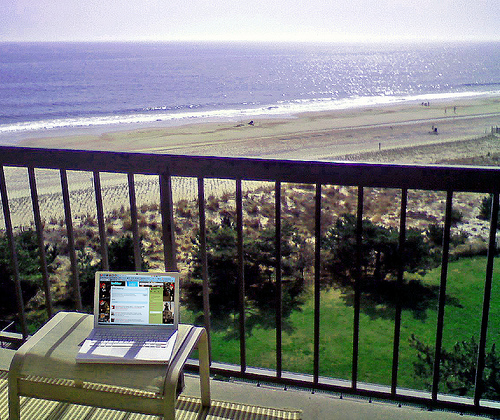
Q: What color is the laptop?
A: White.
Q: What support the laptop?
A: Foot rest.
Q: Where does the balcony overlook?
A: Yard and beach.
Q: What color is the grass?
A: Green.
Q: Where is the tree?
A: By the beach.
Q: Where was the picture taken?
A: On a balcony.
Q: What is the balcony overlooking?
A: The beach.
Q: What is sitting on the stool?
A: A computer.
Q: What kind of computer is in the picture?
A: A laptop.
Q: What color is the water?
A: Blue.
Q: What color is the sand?
A: Tan.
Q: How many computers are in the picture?
A: One.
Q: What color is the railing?
A: Black.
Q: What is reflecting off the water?
A: The sun.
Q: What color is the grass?
A: Green.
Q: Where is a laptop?
A: On a foot stool.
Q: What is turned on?
A: Laptop computer.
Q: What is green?
A: Grass.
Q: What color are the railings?
A: Black.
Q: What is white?
A: The laptop.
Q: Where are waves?
A: In the ocean.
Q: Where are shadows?
A: On the grass.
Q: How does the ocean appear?
A: Calm.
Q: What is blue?
A: The ocean water.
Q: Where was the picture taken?
A: On a balcony.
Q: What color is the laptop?
A: White.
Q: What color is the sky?
A: Blue and white.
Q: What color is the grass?
A: Green.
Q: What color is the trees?
A: Green.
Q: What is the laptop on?
A: Table.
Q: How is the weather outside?
A: Sunny.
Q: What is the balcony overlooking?
A: The ocean.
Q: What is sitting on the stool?
A: A computer.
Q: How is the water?
A: Calm.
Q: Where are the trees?
A: In the grass.